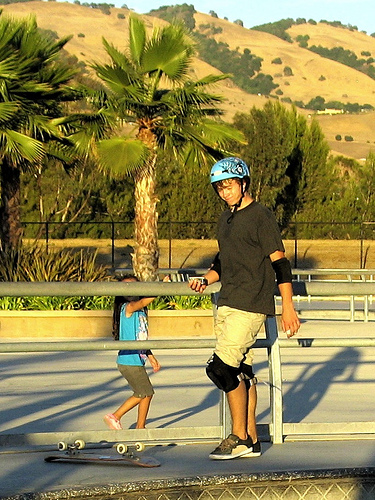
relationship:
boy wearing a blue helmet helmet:
[172, 144, 320, 465] [188, 133, 266, 215]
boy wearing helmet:
[187, 156, 300, 459] [189, 151, 251, 181]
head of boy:
[208, 156, 251, 205] [194, 158, 301, 460]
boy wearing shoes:
[187, 156, 300, 459] [209, 432, 266, 464]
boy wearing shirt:
[172, 144, 320, 465] [208, 217, 291, 303]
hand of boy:
[278, 295, 301, 338] [194, 158, 301, 460]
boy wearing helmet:
[187, 156, 300, 459] [207, 153, 252, 185]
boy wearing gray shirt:
[187, 156, 300, 459] [210, 199, 284, 314]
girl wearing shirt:
[101, 272, 177, 431] [116, 302, 149, 366]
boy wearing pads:
[187, 156, 300, 459] [256, 248, 326, 279]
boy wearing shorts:
[187, 156, 300, 459] [208, 302, 268, 366]